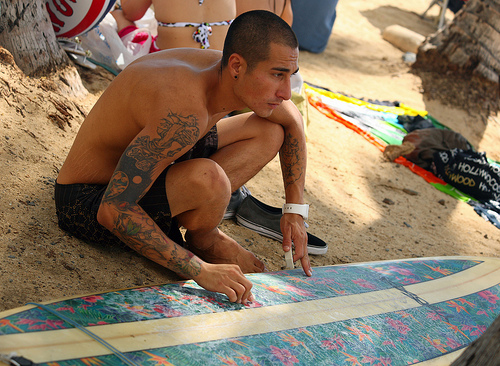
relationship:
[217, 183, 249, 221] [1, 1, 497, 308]
sneakers are on sand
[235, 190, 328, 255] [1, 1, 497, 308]
sneakers are on sand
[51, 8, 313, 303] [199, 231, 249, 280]
man has foot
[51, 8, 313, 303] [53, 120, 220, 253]
man wears black shorts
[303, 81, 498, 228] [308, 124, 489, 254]
towel on sand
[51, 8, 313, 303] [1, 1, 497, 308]
man on sand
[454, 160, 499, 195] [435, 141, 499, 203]
hollywood on object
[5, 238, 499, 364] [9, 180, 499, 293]
surfboard in sand